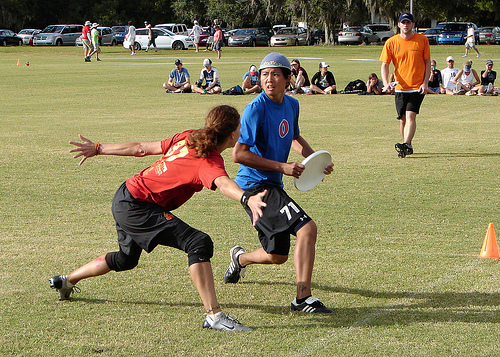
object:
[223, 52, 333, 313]
man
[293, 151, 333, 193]
frisbee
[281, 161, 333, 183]
hands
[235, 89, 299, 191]
shirt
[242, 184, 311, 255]
shorts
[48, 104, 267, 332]
woman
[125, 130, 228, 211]
shirt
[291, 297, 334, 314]
shoe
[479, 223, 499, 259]
cone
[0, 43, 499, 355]
field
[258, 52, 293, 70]
hat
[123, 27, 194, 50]
car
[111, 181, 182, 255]
shorts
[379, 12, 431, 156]
man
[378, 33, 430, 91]
shirt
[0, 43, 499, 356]
grass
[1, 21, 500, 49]
parking lot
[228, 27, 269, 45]
car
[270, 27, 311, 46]
car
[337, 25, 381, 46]
car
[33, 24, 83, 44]
car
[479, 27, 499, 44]
car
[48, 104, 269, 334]
people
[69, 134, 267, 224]
hands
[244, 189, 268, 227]
hand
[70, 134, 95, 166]
hand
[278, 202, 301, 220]
71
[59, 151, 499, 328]
shadows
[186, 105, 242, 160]
hair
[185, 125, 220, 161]
ponytail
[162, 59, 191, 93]
person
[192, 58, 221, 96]
person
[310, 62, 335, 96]
person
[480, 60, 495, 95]
person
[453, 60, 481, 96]
person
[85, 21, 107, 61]
person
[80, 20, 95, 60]
person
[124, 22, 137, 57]
person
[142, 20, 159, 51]
person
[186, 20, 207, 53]
person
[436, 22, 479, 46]
car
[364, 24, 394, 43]
car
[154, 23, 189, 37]
car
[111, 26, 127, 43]
car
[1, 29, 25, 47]
car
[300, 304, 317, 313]
adidas logo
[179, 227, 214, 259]
knee pads